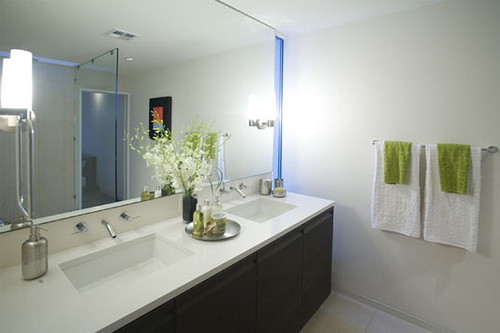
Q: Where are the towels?
A: Rack.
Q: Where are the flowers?
A: Vase.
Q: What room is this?
A: Bathroom.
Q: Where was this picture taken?
A: Bathroom.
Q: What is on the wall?
A: Towels.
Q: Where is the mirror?
A: In front of the sinks.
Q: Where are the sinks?
A: In front of the mirror.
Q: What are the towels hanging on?
A: Metal rod.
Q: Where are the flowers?
A: In a vase.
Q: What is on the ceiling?
A: A vent.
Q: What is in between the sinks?
A: Flowers.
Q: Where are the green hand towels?
A: On top of the large white towels.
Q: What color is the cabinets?
A: Dark brown.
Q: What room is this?
A: Bathroom.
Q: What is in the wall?
A: A mirror.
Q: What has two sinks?
A: The counter.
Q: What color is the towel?
A: White.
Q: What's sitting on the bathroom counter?
A: Flowers.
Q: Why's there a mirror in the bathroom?
A: To see in.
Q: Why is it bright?
A: The light is on.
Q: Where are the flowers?
A: In a vase.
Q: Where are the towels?
A: On the rack.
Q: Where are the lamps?
A: Mounted on the mirror.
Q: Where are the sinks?
A: In the countertop.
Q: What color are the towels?
A: Green and white.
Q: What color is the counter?
A: White.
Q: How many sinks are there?
A: Two.